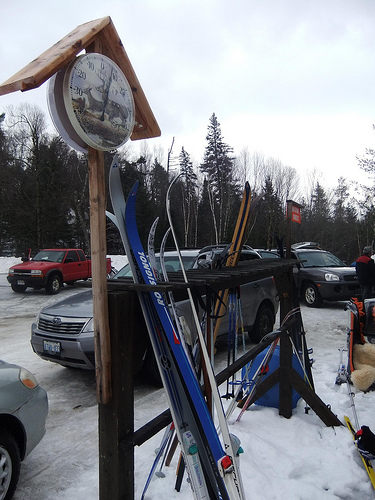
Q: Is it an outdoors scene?
A: Yes, it is outdoors.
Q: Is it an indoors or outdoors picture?
A: It is outdoors.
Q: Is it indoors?
A: No, it is outdoors.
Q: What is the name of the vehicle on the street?
A: The vehicle is a car.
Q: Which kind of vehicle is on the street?
A: The vehicle is a car.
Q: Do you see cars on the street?
A: Yes, there is a car on the street.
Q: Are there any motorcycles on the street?
A: No, there is a car on the street.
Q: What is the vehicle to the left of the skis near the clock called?
A: The vehicle is a car.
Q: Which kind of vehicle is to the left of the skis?
A: The vehicle is a car.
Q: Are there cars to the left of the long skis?
A: Yes, there is a car to the left of the skis.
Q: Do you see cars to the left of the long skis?
A: Yes, there is a car to the left of the skis.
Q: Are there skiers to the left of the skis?
A: No, there is a car to the left of the skis.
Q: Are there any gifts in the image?
A: No, there are no gifts.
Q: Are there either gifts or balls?
A: No, there are no gifts or balls.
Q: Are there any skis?
A: Yes, there are skis.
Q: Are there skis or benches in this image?
A: Yes, there are skis.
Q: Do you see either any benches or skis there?
A: Yes, there are skis.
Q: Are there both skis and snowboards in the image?
A: No, there are skis but no snowboards.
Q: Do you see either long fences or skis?
A: Yes, there are long skis.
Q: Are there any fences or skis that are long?
A: Yes, the skis are long.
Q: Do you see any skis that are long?
A: Yes, there are long skis.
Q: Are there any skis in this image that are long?
A: Yes, there are skis that are long.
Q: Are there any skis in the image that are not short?
A: Yes, there are long skis.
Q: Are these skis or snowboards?
A: These are skis.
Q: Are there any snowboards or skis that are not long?
A: No, there are skis but they are long.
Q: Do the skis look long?
A: Yes, the skis are long.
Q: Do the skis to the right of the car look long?
A: Yes, the skis are long.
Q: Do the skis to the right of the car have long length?
A: Yes, the skis are long.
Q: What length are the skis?
A: The skis are long.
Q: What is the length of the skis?
A: The skis are long.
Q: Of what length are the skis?
A: The skis are long.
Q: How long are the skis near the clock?
A: The skis are long.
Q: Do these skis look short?
A: No, the skis are long.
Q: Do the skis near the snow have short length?
A: No, the skis are long.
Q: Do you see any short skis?
A: No, there are skis but they are long.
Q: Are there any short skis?
A: No, there are skis but they are long.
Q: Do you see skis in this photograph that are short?
A: No, there are skis but they are long.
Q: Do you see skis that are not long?
A: No, there are skis but they are long.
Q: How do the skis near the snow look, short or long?
A: The skis are long.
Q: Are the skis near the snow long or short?
A: The skis are long.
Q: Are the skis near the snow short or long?
A: The skis are long.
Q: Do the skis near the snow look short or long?
A: The skis are long.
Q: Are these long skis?
A: Yes, these are long skis.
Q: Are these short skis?
A: No, these are long skis.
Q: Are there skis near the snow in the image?
A: Yes, there are skis near the snow.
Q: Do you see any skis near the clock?
A: Yes, there are skis near the clock.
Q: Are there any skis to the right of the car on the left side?
A: Yes, there are skis to the right of the car.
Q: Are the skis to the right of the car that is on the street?
A: Yes, the skis are to the right of the car.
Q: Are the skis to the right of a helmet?
A: No, the skis are to the right of the car.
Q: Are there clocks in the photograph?
A: Yes, there is a clock.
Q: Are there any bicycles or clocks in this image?
A: Yes, there is a clock.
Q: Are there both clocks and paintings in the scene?
A: No, there is a clock but no paintings.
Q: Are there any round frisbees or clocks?
A: Yes, there is a round clock.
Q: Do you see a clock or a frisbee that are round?
A: Yes, the clock is round.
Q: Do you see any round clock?
A: Yes, there is a round clock.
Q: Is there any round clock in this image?
A: Yes, there is a round clock.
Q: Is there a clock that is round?
A: Yes, there is a clock that is round.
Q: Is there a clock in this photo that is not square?
A: Yes, there is a round clock.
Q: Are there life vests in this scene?
A: No, there are no life vests.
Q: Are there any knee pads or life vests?
A: No, there are no life vests or knee pads.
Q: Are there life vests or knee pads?
A: No, there are no life vests or knee pads.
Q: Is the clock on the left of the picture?
A: Yes, the clock is on the left of the image.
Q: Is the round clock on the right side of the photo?
A: No, the clock is on the left of the image.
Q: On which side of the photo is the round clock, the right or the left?
A: The clock is on the left of the image.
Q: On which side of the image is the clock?
A: The clock is on the left of the image.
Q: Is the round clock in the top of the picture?
A: Yes, the clock is in the top of the image.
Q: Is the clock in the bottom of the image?
A: No, the clock is in the top of the image.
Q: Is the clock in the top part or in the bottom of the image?
A: The clock is in the top of the image.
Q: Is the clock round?
A: Yes, the clock is round.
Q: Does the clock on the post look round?
A: Yes, the clock is round.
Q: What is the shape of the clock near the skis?
A: The clock is round.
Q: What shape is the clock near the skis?
A: The clock is round.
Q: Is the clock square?
A: No, the clock is round.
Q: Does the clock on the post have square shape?
A: No, the clock is round.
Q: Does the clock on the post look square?
A: No, the clock is round.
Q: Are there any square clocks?
A: No, there is a clock but it is round.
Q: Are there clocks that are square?
A: No, there is a clock but it is round.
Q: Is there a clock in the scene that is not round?
A: No, there is a clock but it is round.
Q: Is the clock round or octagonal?
A: The clock is round.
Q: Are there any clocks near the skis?
A: Yes, there is a clock near the skis.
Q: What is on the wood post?
A: The clock is on the post.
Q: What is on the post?
A: The clock is on the post.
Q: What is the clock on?
A: The clock is on the post.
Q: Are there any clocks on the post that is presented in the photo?
A: Yes, there is a clock on the post.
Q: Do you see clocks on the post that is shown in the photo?
A: Yes, there is a clock on the post.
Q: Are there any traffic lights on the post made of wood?
A: No, there is a clock on the post.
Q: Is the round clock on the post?
A: Yes, the clock is on the post.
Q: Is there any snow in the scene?
A: Yes, there is snow.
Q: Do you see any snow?
A: Yes, there is snow.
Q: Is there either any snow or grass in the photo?
A: Yes, there is snow.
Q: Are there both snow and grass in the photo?
A: No, there is snow but no grass.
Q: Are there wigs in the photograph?
A: No, there are no wigs.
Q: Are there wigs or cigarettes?
A: No, there are no wigs or cigarettes.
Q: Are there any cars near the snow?
A: Yes, there is a car near the snow.